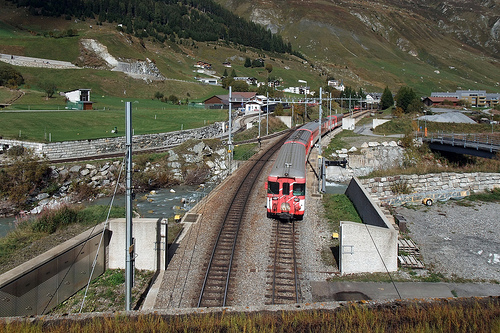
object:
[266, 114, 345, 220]
red train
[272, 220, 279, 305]
track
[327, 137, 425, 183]
wall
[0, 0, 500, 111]
mountain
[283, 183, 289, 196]
windows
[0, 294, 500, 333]
bridge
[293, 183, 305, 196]
window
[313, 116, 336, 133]
cars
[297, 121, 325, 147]
cars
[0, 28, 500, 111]
hillside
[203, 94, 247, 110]
house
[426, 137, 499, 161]
bridge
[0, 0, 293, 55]
forest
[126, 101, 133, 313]
pole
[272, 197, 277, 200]
light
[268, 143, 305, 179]
roof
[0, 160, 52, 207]
bushes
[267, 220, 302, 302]
tracks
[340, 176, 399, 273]
wall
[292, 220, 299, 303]
track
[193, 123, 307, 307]
track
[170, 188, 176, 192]
rock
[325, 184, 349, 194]
creek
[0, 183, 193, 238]
creek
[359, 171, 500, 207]
wall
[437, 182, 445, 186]
stone bricks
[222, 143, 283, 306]
track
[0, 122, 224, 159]
wall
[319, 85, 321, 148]
pole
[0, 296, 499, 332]
grass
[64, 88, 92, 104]
structure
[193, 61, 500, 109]
villiage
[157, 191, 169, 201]
water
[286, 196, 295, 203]
stripe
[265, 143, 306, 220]
car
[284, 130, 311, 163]
car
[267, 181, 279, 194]
window